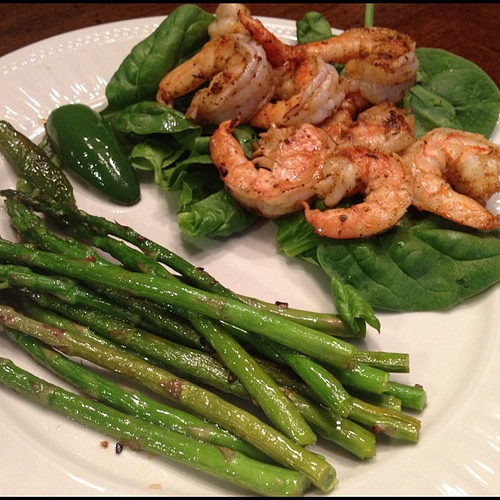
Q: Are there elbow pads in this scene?
A: No, there are no elbow pads.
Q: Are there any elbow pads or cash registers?
A: No, there are no elbow pads or cash registers.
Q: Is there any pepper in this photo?
A: Yes, there is a pepper.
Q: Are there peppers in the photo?
A: Yes, there is a pepper.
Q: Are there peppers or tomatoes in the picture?
A: Yes, there is a pepper.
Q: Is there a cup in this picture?
A: No, there are no cups.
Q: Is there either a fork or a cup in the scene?
A: No, there are no cups or forks.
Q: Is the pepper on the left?
A: Yes, the pepper is on the left of the image.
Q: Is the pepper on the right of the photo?
A: No, the pepper is on the left of the image.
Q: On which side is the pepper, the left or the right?
A: The pepper is on the left of the image.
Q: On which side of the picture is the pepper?
A: The pepper is on the left of the image.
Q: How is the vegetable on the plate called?
A: The vegetable is a pepper.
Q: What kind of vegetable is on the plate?
A: The vegetable is a pepper.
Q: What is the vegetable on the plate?
A: The vegetable is a pepper.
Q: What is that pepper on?
A: The pepper is on the plate.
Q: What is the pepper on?
A: The pepper is on the plate.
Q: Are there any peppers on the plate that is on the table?
A: Yes, there is a pepper on the plate.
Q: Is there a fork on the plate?
A: No, there is a pepper on the plate.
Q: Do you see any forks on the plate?
A: No, there is a pepper on the plate.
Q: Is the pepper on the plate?
A: Yes, the pepper is on the plate.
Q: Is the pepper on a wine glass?
A: No, the pepper is on the plate.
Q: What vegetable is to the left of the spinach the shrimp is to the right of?
A: The vegetable is a pepper.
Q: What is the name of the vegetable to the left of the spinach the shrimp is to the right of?
A: The vegetable is a pepper.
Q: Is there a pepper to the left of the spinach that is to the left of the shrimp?
A: Yes, there is a pepper to the left of the spinach.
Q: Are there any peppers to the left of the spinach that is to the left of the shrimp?
A: Yes, there is a pepper to the left of the spinach.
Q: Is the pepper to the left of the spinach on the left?
A: Yes, the pepper is to the left of the spinach.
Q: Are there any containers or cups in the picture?
A: No, there are no cups or containers.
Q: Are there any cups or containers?
A: No, there are no cups or containers.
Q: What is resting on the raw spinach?
A: The shrimp is resting on the spinach.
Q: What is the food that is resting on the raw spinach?
A: The food is shrimp.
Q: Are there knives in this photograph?
A: No, there are no knives.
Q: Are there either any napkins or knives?
A: No, there are no knives or napkins.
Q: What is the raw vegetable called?
A: The vegetable is spinach.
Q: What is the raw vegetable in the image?
A: The vegetable is spinach.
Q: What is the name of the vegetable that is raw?
A: The vegetable is spinach.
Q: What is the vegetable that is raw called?
A: The vegetable is spinach.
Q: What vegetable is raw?
A: The vegetable is spinach.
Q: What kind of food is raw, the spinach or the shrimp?
A: The spinach is raw.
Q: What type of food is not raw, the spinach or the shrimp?
A: The shrimp is not raw.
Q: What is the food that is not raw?
A: The food is shrimp.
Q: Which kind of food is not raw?
A: The food is shrimp.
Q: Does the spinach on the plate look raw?
A: Yes, the spinach is raw.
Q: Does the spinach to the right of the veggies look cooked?
A: No, the spinach is raw.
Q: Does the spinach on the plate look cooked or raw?
A: The spinach is raw.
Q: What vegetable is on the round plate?
A: The vegetable is spinach.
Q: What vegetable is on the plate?
A: The vegetable is spinach.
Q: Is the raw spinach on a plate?
A: Yes, the spinach is on a plate.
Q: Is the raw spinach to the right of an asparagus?
A: Yes, the spinach is to the right of an asparagus.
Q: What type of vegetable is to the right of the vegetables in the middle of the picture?
A: The vegetable is spinach.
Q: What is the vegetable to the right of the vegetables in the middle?
A: The vegetable is spinach.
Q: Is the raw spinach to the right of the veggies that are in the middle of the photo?
A: Yes, the spinach is to the right of the vegetables.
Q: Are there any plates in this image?
A: Yes, there is a plate.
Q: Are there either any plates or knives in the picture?
A: Yes, there is a plate.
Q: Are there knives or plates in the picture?
A: Yes, there is a plate.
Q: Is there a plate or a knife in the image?
A: Yes, there is a plate.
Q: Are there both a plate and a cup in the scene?
A: No, there is a plate but no cups.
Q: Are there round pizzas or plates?
A: Yes, there is a round plate.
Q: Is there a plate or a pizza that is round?
A: Yes, the plate is round.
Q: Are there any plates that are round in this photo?
A: Yes, there is a round plate.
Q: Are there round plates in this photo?
A: Yes, there is a round plate.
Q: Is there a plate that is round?
A: Yes, there is a plate that is round.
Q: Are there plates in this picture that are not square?
A: Yes, there is a round plate.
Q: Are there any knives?
A: No, there are no knives.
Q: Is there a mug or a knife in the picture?
A: No, there are no knives or mugs.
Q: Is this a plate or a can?
A: This is a plate.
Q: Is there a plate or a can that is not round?
A: No, there is a plate but it is round.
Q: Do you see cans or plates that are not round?
A: No, there is a plate but it is round.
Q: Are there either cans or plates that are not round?
A: No, there is a plate but it is round.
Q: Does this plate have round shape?
A: Yes, the plate is round.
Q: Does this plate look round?
A: Yes, the plate is round.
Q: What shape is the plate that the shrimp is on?
A: The plate is round.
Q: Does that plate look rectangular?
A: No, the plate is round.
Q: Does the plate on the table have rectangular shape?
A: No, the plate is round.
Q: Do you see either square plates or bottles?
A: No, there is a plate but it is round.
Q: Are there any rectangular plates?
A: No, there is a plate but it is round.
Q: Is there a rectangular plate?
A: No, there is a plate but it is round.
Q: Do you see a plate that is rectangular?
A: No, there is a plate but it is round.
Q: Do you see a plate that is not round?
A: No, there is a plate but it is round.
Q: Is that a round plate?
A: Yes, that is a round plate.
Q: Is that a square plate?
A: No, that is a round plate.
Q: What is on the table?
A: The plate is on the table.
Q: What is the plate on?
A: The plate is on the table.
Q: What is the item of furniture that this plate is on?
A: The piece of furniture is a table.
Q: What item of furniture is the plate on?
A: The plate is on the table.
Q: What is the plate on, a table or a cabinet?
A: The plate is on a table.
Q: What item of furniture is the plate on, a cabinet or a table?
A: The plate is on a table.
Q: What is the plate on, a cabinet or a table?
A: The plate is on a table.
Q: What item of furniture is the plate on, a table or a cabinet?
A: The plate is on a table.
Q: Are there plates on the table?
A: Yes, there is a plate on the table.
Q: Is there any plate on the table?
A: Yes, there is a plate on the table.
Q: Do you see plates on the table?
A: Yes, there is a plate on the table.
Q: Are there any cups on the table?
A: No, there is a plate on the table.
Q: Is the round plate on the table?
A: Yes, the plate is on the table.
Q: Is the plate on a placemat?
A: No, the plate is on the table.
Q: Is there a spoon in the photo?
A: No, there are no spoons.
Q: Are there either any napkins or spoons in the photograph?
A: No, there are no spoons or napkins.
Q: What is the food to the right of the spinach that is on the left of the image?
A: The food is shrimp.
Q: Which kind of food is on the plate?
A: The food is shrimp.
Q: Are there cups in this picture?
A: No, there are no cups.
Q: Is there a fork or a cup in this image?
A: No, there are no cups or forks.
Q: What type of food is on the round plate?
A: The food is shrimp.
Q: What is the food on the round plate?
A: The food is shrimp.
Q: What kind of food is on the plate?
A: The food is shrimp.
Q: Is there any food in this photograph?
A: Yes, there is food.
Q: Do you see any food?
A: Yes, there is food.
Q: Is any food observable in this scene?
A: Yes, there is food.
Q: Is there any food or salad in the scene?
A: Yes, there is food.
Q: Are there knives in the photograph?
A: No, there are no knives.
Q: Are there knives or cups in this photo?
A: No, there are no knives or cups.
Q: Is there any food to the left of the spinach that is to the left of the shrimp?
A: Yes, there is food to the left of the spinach.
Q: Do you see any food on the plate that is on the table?
A: Yes, there is food on the plate.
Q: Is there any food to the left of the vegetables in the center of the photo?
A: Yes, there is food to the left of the vegetables.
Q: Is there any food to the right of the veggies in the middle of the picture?
A: No, the food is to the left of the veggies.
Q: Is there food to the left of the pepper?
A: Yes, there is food to the left of the pepper.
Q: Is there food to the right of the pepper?
A: No, the food is to the left of the pepper.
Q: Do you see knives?
A: No, there are no knives.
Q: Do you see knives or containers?
A: No, there are no knives or containers.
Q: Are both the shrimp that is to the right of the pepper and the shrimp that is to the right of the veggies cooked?
A: Yes, both the shrimp and the shrimp are cooked.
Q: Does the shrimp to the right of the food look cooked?
A: Yes, the shrimp is cooked.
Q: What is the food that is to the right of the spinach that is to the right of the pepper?
A: The food is shrimp.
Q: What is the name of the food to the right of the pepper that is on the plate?
A: The food is shrimp.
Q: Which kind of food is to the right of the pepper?
A: The food is shrimp.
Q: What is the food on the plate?
A: The food is shrimp.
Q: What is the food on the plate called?
A: The food is shrimp.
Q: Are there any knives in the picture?
A: No, there are no knives.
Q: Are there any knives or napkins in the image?
A: No, there are no knives or napkins.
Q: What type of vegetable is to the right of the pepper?
A: The vegetable is spinach.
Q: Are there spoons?
A: No, there are no spoons.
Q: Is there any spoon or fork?
A: No, there are no spoons or forks.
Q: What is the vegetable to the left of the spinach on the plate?
A: The vegetable is an asparagus.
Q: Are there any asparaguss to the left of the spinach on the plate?
A: Yes, there is an asparagus to the left of the spinach.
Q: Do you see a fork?
A: No, there are no forks.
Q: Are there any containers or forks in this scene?
A: No, there are no forks or containers.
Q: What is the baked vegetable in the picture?
A: The vegetable is an asparagus.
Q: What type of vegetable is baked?
A: The vegetable is an asparagus.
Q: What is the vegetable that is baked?
A: The vegetable is an asparagus.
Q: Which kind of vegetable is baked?
A: The vegetable is an asparagus.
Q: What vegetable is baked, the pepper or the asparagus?
A: The asparagus is baked.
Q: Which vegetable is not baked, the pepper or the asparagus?
A: The pepper is not baked.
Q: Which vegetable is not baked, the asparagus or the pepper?
A: The pepper is not baked.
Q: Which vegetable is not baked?
A: The vegetable is a pepper.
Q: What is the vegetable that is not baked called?
A: The vegetable is a pepper.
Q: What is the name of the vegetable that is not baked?
A: The vegetable is a pepper.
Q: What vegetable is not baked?
A: The vegetable is a pepper.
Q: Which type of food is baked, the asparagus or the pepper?
A: The asparagus is baked.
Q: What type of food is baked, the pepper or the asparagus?
A: The asparagus is baked.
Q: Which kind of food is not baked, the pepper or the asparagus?
A: The pepper is not baked.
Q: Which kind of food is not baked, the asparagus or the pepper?
A: The pepper is not baked.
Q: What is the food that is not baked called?
A: The food is a pepper.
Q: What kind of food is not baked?
A: The food is a pepper.